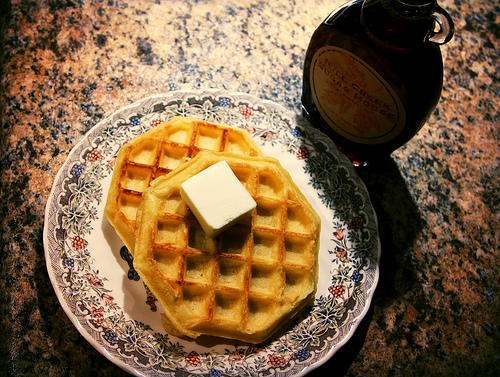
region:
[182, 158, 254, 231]
a square of butter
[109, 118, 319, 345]
two waffles on a plate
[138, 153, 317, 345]
a affle with butter on it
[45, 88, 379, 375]
a plate with intricate designs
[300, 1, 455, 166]
a bottle of maple syrup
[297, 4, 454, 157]
a maple syrup bottle on a marble surface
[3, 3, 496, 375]
a marble surface with black and orange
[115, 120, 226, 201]
burned bits on a waffle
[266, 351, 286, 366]
a bunch of red grapes drawn on a plate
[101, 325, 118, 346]
a bunch of blue grapes drawn on a plate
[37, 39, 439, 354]
small waffles on a plate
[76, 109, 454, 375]
a slice of butter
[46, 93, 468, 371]
butter on top of waffles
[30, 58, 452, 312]
a plate with waffles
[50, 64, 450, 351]
a plate on a table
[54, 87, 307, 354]
a plate with two waffles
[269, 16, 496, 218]
syrup on the table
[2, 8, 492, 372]
a table with syrup and waffles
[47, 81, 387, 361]
waffles and butter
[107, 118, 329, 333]
two waffles on a plate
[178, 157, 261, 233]
butter on the waffles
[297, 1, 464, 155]
syrup next to the plate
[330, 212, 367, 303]
berry design on the plate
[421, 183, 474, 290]
marble table top the dish is on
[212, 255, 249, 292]
square in the waffle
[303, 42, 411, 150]
sticker on the syrup bottle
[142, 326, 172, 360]
leaf design on the plate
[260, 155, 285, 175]
edge of the waffle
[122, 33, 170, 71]
black spots on the table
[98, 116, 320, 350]
Waffles on a plate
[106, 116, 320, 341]
Waffles are on a plate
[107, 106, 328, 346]
Waffles on a round plate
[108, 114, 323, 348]
Waffles are on a round plate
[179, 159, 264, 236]
Butter on waffles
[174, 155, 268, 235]
Butter is on waffles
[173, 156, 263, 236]
Slice of butter on waffles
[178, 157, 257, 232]
Slice of butter is on waffles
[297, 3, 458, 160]
Syrup on the counter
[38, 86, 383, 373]
Plate on the counter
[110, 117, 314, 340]
to octagon waffles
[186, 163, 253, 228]
a large pat of butter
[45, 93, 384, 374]
a round plate with floral pattern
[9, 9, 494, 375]
a dark granite counter top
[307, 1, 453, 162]
a jar of maple syrup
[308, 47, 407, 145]
the label on the the syrup jar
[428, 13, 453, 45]
the glass handle on the jar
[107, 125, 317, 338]
waffles with some butter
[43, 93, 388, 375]
two waffles on a plate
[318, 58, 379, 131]
orange leaves on the syrup label